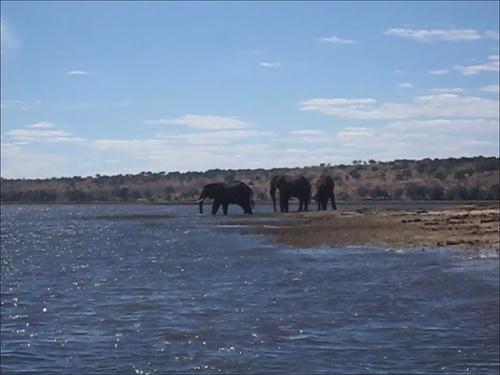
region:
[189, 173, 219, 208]
head of an elephant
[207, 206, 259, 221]
legs of an elephant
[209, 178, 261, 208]
body of an elephant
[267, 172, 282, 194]
head of an elephant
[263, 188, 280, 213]
nose of an elephant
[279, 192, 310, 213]
legs of an elephant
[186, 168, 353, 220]
three elephants on a field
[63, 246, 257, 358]
a clear body of water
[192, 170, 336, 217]
Three tall elephants by the water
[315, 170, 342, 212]
An elephant facing away from the camera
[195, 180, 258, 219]
An elephant stepping into the water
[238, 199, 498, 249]
The shore next to the water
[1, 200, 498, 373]
A large body of water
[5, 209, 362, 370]
Light shining on the water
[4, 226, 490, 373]
Ripples in the water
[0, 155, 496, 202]
A hill of trees across the water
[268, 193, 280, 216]
An elephant's trunk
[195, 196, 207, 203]
An elephant's white tusk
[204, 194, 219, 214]
leg on large elephant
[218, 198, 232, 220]
leg on large elephant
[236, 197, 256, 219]
leg on large elephant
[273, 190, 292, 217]
leg on large elephant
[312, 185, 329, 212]
leg on large elephant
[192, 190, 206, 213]
large trunk on elephant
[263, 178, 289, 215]
large trunk on elephant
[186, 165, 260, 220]
large elephant near water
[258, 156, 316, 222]
large elephant near water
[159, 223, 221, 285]
ripples in clear water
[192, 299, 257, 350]
ripples in clear water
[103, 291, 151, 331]
ripples in clear water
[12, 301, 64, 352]
ripples in clear water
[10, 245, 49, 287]
ripples in clear water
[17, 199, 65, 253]
ripples in clear water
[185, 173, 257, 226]
elephant walking on water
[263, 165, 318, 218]
elephant walking on water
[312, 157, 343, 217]
elephant walking on water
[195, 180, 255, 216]
Elephant standing in water.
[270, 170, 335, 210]
Two elephants on the land.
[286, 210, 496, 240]
Brown, damp sand bar.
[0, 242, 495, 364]
Blue rippling water elephant is drinking from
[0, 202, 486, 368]
Watering hole for elephants.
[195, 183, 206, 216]
Elephant trunk and tusk.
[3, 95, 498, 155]
Thin wispy clouds.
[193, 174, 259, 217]
a large grey elephant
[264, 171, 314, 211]
a large grey elephant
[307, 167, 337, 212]
a large grey elephant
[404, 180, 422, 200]
a tree in a field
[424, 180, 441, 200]
a tree in a field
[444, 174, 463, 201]
a tree in a field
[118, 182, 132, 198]
a tree in a field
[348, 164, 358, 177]
a tree in a field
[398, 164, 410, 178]
a tree in a field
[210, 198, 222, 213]
grey leg of elephant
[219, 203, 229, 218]
grey leg of elephant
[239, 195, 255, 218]
grey leg of elephant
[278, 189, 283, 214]
grey leg of elephant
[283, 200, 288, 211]
grey leg of elephant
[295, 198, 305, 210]
grey leg of elephant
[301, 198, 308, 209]
grey leg of elephant